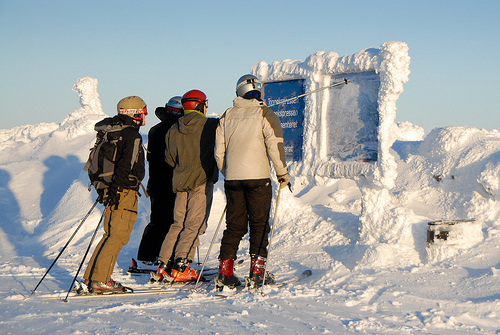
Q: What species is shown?
A: Homo sapiens.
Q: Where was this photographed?
A: Mountain.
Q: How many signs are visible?
A: Two.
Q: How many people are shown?
A: Four.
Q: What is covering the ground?
A: Snow.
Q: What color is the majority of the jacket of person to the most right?
A: White.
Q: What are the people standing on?
A: The ground.